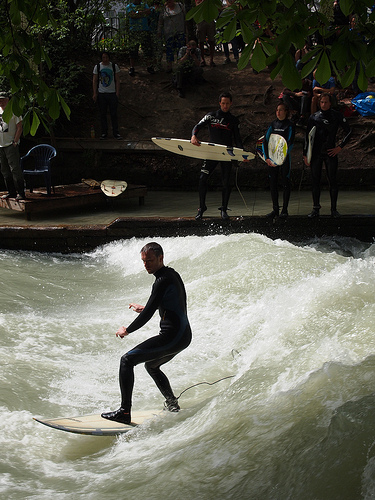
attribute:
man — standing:
[84, 49, 131, 139]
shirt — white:
[90, 60, 127, 96]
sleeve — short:
[86, 62, 104, 82]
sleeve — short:
[110, 64, 124, 80]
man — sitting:
[172, 38, 210, 106]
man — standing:
[189, 88, 247, 222]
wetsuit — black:
[193, 110, 238, 211]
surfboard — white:
[146, 132, 258, 168]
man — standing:
[299, 93, 355, 222]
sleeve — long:
[187, 110, 217, 139]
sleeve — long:
[332, 112, 356, 150]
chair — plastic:
[15, 140, 63, 195]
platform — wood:
[0, 177, 151, 223]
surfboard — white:
[97, 177, 131, 199]